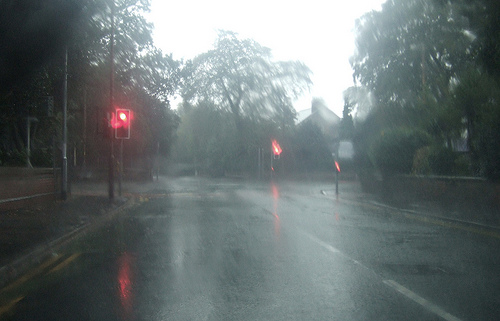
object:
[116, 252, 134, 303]
light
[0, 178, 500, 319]
ground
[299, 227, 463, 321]
line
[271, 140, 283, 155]
street light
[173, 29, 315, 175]
tree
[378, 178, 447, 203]
barrier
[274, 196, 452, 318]
white line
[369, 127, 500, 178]
bush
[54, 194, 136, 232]
corner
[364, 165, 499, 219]
stone wall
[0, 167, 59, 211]
brick wall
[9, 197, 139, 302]
curb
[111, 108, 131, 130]
blurry/red light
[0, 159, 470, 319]
no cars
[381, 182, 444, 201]
wall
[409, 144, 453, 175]
trimmed bushes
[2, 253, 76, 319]
double lines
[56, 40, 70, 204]
large/gray pole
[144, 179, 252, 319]
wet/shiny pavement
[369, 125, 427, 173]
green bushes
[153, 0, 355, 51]
white/bright sky